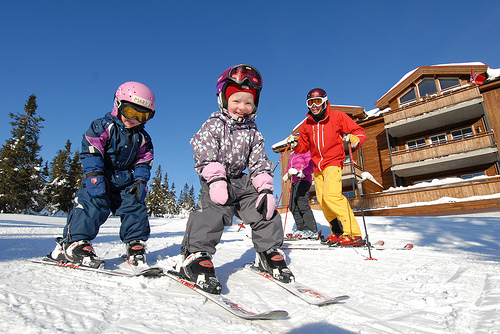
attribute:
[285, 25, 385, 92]
sky — blue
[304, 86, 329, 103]
helmet — red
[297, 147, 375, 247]
pants — yellow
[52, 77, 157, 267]
girl — young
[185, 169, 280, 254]
pants — gray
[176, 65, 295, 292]
child — smiling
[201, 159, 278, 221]
gloves — pink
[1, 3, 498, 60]
sky — blue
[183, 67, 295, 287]
kid — young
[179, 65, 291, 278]
kid — young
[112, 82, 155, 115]
helmet — pink